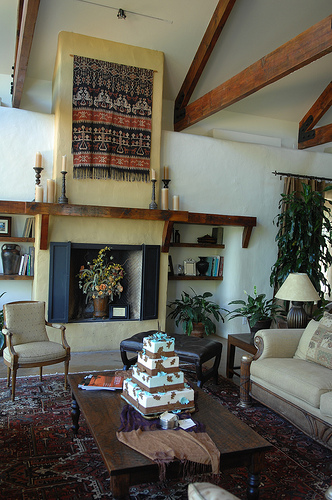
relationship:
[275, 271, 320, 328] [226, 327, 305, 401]
lamp on table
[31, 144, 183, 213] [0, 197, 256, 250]
candles on table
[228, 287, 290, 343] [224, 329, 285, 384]
plant on table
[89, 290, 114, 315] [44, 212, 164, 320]
potted in fireplace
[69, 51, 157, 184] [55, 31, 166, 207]
fabric hanging on wall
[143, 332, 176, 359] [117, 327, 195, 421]
section of a cake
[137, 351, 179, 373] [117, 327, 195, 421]
section of a cake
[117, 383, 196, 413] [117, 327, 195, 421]
section of a cake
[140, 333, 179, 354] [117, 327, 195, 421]
section of a cake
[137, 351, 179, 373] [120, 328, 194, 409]
section of a cake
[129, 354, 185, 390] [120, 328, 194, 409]
section of a cake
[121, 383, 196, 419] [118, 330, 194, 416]
section of a cake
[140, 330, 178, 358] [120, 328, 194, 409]
section of a cake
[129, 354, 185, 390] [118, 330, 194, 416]
section of a cake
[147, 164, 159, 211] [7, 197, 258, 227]
candle on a shelf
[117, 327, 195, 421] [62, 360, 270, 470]
cake on a table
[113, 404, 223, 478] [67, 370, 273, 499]
blanket on a coffee table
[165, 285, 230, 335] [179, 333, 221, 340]
plant on a table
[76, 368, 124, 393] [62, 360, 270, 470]
book on a table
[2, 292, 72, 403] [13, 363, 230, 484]
chair that is on a rug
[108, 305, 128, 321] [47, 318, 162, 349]
paper on a shelf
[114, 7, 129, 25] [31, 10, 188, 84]
light on the ceiling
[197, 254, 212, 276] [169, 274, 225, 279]
vase on the shelf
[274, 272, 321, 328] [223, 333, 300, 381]
lamp on the table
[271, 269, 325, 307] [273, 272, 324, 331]
shade on lamp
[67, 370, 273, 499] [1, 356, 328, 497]
coffee table on rug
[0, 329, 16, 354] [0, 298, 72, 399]
armrests on chair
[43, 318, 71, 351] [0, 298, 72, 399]
armrests on chair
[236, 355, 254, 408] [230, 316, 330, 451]
leg on couch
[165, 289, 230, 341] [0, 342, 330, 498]
plant on floor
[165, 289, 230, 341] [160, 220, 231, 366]
plant on nook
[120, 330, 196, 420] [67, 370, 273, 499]
cake on coffee table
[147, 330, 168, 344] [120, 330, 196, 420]
trimmings on cake